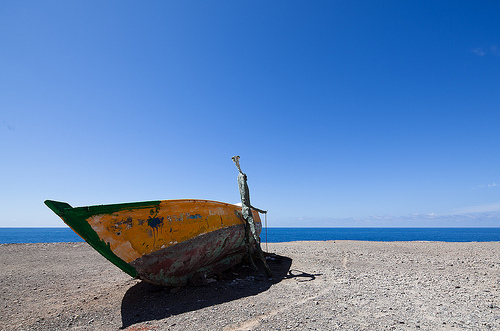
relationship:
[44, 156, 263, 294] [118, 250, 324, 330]
boat making shadow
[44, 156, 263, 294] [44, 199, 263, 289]
boat has edges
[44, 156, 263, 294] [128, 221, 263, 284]
boat has rust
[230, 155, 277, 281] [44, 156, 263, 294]
object next to boat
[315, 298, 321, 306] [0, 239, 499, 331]
rock on sand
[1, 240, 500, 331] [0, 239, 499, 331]
rocks on sand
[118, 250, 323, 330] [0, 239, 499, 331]
shadow on sand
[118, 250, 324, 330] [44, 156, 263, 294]
shadow next to boat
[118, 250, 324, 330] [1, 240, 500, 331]
shadow on rocks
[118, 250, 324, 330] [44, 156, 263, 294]
shadow near boat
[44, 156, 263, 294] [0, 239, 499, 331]
boat on sand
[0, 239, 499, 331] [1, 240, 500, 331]
beach has rocks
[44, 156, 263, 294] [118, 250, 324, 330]
boat making a shadow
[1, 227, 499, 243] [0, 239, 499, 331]
water at sand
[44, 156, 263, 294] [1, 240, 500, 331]
boat on rocks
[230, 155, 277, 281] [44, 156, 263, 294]
object standing against boat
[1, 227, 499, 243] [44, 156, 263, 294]
water behind boat